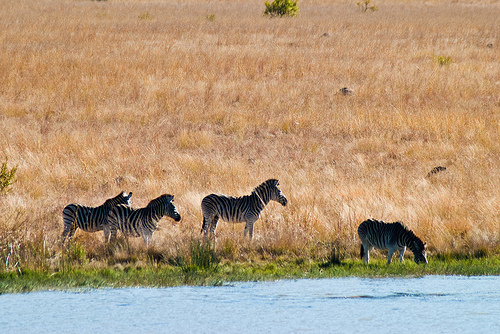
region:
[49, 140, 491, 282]
four zebras in a field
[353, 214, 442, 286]
zebra eating grass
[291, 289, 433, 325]
water is calm and blue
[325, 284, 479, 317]
zebra's reflection on water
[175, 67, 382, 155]
grass is dry and brown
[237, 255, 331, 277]
grass is lush and green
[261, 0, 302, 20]
small tree in field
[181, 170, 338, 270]
zebra walking through field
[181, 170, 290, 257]
black and white stripes on zebra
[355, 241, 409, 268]
white legs of zebra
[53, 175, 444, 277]
four zebras in the grass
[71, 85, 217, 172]
the grass is tall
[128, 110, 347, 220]
the grass is dry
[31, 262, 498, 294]
the green grass beside the water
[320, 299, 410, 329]
the water is calm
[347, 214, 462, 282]
the zebra is drinking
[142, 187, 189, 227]
the head of the zebra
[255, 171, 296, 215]
the head of the zebra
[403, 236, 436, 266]
the head of the zebra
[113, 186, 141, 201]
the head of the zebra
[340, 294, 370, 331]
part of a water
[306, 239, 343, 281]
part of a grass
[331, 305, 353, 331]
part of a water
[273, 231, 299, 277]
part of a ground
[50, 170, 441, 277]
zebras in a field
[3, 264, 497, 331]
water in front of the zebras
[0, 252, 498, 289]
green grass by the water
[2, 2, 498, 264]
brown grass behind the green grass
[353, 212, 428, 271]
this zebra is eating green grass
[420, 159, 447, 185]
an object in the grass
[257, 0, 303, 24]
a green plant in the brown grass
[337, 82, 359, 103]
a rock in the brown grass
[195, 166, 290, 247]
this zebra is standing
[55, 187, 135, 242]
this zebra is behind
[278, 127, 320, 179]
part of a grass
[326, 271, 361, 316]
part of a water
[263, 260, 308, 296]
edge of a shore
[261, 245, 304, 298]
part of a grass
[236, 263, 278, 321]
part of a water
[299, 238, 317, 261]
part of a grass